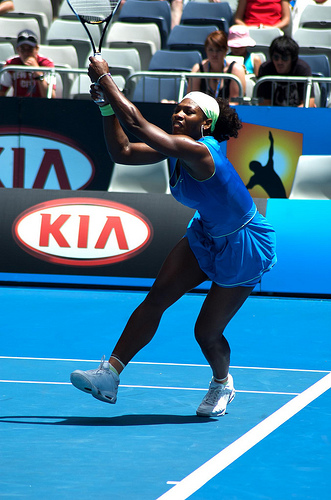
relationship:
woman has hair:
[70, 56, 277, 421] [199, 90, 241, 143]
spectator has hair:
[186, 28, 247, 106] [205, 31, 228, 52]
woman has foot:
[70, 56, 277, 421] [195, 375, 236, 418]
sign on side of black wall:
[10, 195, 155, 267] [2, 185, 195, 280]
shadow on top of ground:
[1, 412, 227, 426] [3, 287, 330, 499]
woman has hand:
[70, 56, 277, 421] [87, 53, 140, 138]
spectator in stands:
[199, 21, 249, 101] [2, 6, 330, 108]